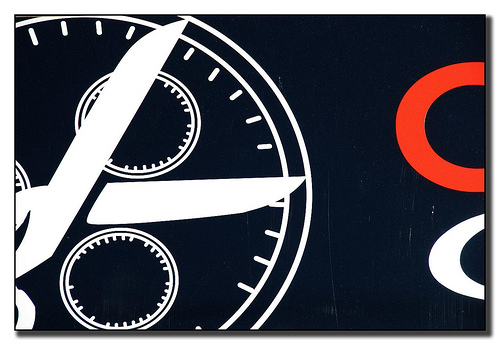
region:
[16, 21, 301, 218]
white scissors over white circle with inner lines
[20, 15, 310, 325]
scissors within larger circle with two borders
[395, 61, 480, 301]
thick red curve over thick white curve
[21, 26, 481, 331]
white and red shapes on black background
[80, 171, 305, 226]
curved edge, point, straight edge and slanted edge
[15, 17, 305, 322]
scissors cutting symbolic time piece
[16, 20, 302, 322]
scissors as replacement hands on a clock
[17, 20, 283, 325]
short inner lines marking passage of time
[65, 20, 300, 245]
blades telling the time of 3:03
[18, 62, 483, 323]
curves representing the missing handles on scissors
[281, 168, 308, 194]
The sharp edge on a scissor blade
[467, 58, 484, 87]
A large red "C" shape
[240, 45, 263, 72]
A white circle edge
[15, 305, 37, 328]
The handle of a scissor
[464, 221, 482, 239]
A white oval shape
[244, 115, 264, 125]
White dashes on a dial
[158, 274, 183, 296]
Interlocking circle shapes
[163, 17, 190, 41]
The top of a scissor blade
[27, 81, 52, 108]
Black interior of a dial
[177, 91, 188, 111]
Hash marks on the inside of a dial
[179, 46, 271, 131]
four white tick marks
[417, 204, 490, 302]
thick white line that is curved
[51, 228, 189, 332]
white circle that's black on the inside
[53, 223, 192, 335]
white tick marks around the circumference of the circle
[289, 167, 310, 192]
tip of the object is sharp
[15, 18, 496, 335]
artwork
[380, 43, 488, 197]
part of a red circle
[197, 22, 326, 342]
two parallel white lines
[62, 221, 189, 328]
thin black line between the two parallel white lines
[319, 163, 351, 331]
faint white line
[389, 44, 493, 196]
Bright red half circle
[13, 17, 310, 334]
Pair of white stencil scissors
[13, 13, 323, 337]
All white line gauge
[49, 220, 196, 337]
Small white ling gauge in the bigger gauge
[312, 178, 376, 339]
Stratch mark in the black paint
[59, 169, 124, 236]
Shadow effect on the pair of scissors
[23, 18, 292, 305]
White dashes going in a circle motion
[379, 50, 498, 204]
Only thing colored in the picture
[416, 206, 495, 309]
White half oval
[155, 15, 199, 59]
Sharp tip of the scissor blade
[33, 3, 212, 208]
a picture of scissors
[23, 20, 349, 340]
a picture of open scissors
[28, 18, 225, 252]
a picture of white scissors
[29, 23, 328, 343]
a picture of white open scissors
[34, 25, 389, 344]
picture of a guage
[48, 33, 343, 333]
picture of scissors and a circle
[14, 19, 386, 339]
picture of white circles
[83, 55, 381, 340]
a white pair of scissors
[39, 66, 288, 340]
a pair of scissors that are open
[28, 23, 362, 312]
an open pair of scissors